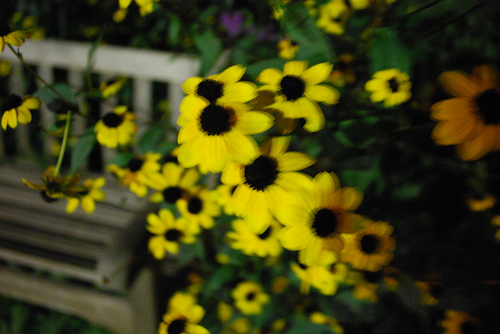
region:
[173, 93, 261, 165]
Yellow and black flower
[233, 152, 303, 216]
Yellow and black flower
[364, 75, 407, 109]
Yellow and black flower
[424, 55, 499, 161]
Yellow and black flower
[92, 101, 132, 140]
Yellow and black flower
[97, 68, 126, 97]
Yellow and black flower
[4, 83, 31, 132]
Yellow and black flower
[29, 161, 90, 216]
Yellow and black flower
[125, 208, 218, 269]
Yellow and black flower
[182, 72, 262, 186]
yellow flower on plant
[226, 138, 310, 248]
yellow flower on plant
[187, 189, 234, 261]
yellow flower on plant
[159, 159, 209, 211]
yellow flower on plant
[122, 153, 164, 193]
yellow flower on plant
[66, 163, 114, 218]
yellow flower on plant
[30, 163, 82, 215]
yellow flower on plant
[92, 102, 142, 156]
yellow flower on plant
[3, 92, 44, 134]
yellow flower on plant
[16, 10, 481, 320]
flowers growing by seating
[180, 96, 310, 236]
yellow petals around black centers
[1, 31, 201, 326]
wooden bench made of slats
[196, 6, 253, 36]
purple flower between green leaves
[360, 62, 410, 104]
flower pointing in one direction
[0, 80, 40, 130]
flower with petals drooping down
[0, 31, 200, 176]
vertical bars on back of bench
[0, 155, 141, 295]
horizontal bars on seat of bench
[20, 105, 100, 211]
flowers facing downward on long stem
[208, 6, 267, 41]
purple flower in the background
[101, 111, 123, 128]
black part is middle of flower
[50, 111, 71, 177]
the flower stem is green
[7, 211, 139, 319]
the bench is wooden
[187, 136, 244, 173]
the peddles of the flower are yellow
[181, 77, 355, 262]
a group of yellow flowers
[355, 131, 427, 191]
a bunch of green leaves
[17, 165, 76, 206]
the flower is facing down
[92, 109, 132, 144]
the flower is pointing up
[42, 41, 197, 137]
back part of a bench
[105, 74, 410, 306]
yellow and black flowers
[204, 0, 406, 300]
green leaves on flowers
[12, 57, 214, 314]
bench is light brown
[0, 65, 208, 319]
grey bench is wooden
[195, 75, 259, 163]
brown center of flowers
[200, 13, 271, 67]
purple flower in background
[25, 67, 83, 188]
thin stems on flowers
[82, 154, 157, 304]
wooden armrest on bench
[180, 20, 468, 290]
flowers to right of bench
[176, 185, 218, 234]
A flower on a stem.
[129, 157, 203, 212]
A flower on a stem.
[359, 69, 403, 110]
A flower on a stem.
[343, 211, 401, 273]
A flower on a stem.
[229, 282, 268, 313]
A flower on a stem.